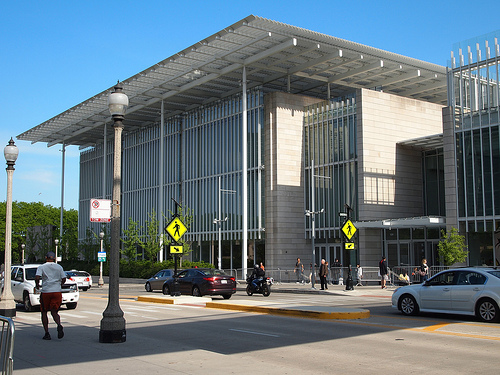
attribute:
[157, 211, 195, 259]
crosswalk sign — yellow, pedestrian, white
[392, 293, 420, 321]
tire — black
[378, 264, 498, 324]
car — white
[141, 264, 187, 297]
car — grey, silver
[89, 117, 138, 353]
pole — grey, tall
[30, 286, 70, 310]
shorts — red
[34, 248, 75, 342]
man — jogging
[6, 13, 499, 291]
building — stone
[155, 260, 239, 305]
car — red, dark red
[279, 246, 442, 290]
people — waiting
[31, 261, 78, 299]
shirt — white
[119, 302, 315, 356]
line — white, painted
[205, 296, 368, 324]
crub — painted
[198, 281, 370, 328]
curb — yellow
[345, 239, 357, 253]
arrow — pointing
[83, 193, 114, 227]
sign — red, white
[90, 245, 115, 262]
sign — green, white